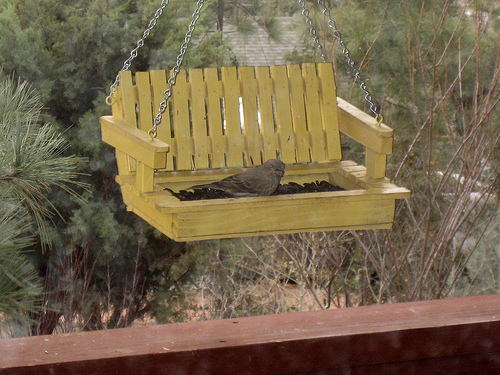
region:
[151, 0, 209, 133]
A grey metal chain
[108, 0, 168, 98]
A grey metal chain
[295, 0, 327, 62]
A grey metal chain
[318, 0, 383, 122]
A grey metal chain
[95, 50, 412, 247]
A small wooden bird house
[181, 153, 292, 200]
a small bird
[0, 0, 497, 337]
A small wooded area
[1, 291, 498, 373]
A wooden guard rail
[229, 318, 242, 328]
A hole in some wood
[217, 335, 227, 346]
A hole in some wood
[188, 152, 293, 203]
small brown feathered bird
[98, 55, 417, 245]
miniature bench bird feeder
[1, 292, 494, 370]
maroon painted wooden board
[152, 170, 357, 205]
bird food in a bird feeder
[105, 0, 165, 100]
small silver metal chain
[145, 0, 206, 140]
small silver metal chain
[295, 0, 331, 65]
small silver metal chain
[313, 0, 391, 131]
small silver metal chain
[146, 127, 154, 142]
small yellow eye hook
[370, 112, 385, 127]
small yellow eye hook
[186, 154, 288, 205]
little light brown bird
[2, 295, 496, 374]
edge of brown painted board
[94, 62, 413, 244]
miniature bird feeder bench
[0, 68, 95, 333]
part of an ever green tree branch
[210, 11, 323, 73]
shingled roof of a distant house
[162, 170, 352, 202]
bird food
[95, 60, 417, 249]
Yellow bench for bird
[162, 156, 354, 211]
Black dirt in the hole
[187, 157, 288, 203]
Small bird in the dirt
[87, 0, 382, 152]
Gray chains holding the bench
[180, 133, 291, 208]
Small brown and grey bird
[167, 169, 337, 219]
Bird seed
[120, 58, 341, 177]
Wooden back rest on bench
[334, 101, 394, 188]
Wooden armrest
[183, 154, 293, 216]
Small bird eating food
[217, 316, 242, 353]
Two nails in wood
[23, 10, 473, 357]
backyard in a rural area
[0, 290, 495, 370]
low wooden wall painted red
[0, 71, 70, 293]
bough of a pine tree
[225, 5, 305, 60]
sloping roof of a house in the background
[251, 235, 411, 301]
bare branches of a bush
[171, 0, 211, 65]
joined links of a chain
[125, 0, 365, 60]
four sections of chains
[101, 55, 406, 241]
bird house built like a swinging bench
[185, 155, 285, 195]
bird sitting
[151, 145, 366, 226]
bird resting on the inset of the bench's seat